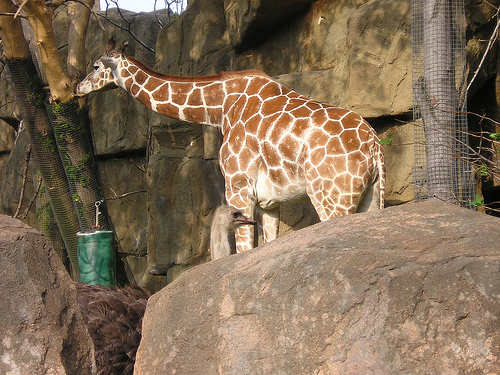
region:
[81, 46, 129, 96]
THE HEAD OF THE GIRAFFE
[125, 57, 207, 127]
THE NECK OF THE GIRAFFE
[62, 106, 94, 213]
THIS IS A TREE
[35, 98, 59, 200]
THIS IS A TREE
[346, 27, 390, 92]
THIS IS A ROCK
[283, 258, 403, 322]
THIS IS A ROCK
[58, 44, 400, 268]
a giraffe color brown and white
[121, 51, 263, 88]
a short mane over the neck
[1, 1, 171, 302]
head of giraffe liking a trunk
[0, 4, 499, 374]
the pen of a giraffe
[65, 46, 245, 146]
neck of giraffe is down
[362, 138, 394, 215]
tail of giraffe is back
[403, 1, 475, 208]
a trunk of a tree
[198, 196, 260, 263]
the head of the bird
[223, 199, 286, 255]
front of legs of giraffe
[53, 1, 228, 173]
branches behind the giraffe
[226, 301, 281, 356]
THIS IS A ROCK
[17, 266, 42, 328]
THIS IS A ROCK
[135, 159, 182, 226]
THIS IS A ROCK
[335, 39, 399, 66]
THIS IS A ROCK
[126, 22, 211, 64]
THIS IS A ROCK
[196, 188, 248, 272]
THIS IS AN OSTRICH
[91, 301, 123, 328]
THESE ARE FEATHERS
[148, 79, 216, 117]
THE NECK OF THE GIRAFFE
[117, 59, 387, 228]
brown and white giraffe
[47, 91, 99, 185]
green moss on tree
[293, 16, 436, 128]
brown rocks behind giraffe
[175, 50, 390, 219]
brown and white spots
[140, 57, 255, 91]
giraffe has brown mane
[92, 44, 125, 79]
giraffe has white ears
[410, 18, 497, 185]
grey mesh fence behind giraffe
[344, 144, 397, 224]
giraffe has brown tail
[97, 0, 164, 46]
bare tree above giraffe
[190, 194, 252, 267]
emu in front of giraffe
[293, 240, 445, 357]
the rock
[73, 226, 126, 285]
a green trashcan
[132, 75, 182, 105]
the neck on the giraffe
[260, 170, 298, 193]
belly of the giraffe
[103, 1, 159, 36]
tree branches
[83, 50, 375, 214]
the giraffe is tall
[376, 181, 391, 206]
tail of the giraffe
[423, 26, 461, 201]
a long tree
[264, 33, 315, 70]
shadow on the rock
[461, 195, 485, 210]
a gree leaf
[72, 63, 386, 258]
a giraffe standin goutside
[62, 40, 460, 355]
a giraffe with neck bent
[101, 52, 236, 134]
a giraffe with long neck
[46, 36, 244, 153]
a giraffe eating a tree